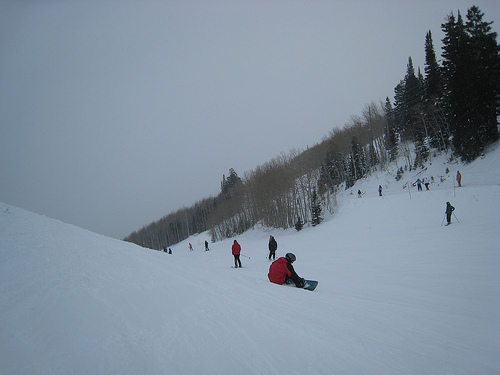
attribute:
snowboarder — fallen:
[264, 250, 319, 291]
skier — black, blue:
[441, 200, 459, 226]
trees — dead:
[122, 108, 397, 250]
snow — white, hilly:
[9, 129, 484, 366]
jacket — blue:
[414, 177, 426, 189]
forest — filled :
[383, 8, 484, 161]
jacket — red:
[224, 241, 240, 254]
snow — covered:
[2, 209, 462, 371]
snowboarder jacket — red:
[266, 250, 290, 288]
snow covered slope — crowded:
[327, 192, 499, 344]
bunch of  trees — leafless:
[202, 147, 321, 244]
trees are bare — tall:
[228, 156, 320, 237]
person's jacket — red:
[227, 239, 245, 260]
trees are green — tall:
[412, 0, 499, 164]